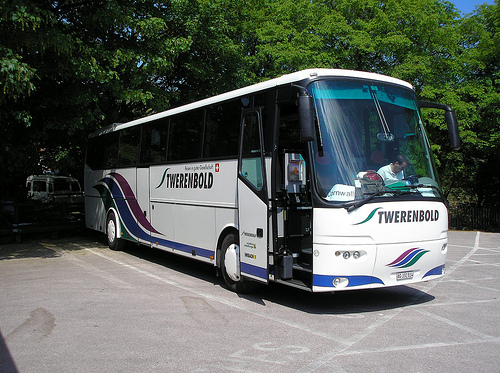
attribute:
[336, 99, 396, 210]
wiper — black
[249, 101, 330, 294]
door — open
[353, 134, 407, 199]
shirt — white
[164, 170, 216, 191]
writing — black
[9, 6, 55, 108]
leaves — green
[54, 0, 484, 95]
sky — blue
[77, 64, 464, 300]
bus — white, parked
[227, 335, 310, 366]
es — faint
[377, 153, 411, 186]
man — brown haired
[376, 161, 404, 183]
shirt — white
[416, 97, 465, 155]
mirror — black, rear view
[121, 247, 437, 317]
shadow — black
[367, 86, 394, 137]
wipers — windshield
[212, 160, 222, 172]
square — red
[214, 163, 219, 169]
cross — white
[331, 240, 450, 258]
headlights — small, round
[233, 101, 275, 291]
door — open, bus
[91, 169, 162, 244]
stripes — green, blue, purple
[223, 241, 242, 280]
caps — white, hub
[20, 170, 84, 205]
van — white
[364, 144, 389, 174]
seat — driver's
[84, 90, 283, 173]
windows — tinted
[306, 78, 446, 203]
windshield — large, clear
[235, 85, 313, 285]
door — open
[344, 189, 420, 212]
windshield wiper — black, folded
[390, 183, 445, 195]
windshield wiper — black, folded